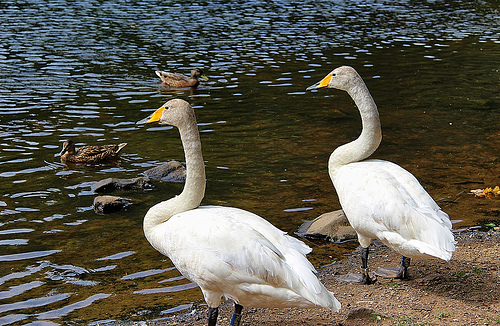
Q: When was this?
A: Daytime.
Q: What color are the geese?
A: White.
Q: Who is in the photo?
A: No one.